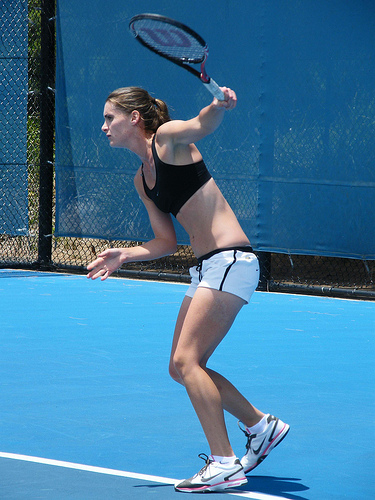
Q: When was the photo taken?
A: Afternoon.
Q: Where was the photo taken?
A: Tennis court.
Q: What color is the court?
A: Blue.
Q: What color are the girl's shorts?
A: White.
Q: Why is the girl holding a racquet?
A: To hit.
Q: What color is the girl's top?
A: Black.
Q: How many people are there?
A: One.